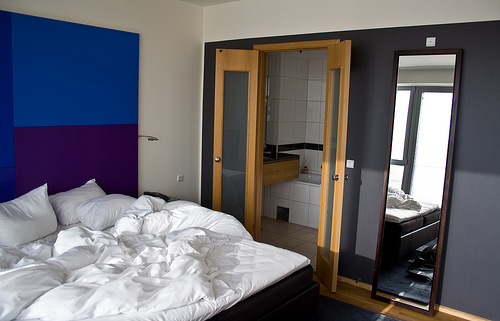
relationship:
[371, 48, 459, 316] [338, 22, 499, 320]
mirror on wall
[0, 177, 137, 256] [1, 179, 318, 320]
pillows on bed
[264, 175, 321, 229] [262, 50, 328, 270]
tub in bathroom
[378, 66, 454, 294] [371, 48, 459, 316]
reflection in mirror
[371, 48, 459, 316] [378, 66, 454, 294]
mirror with a reflection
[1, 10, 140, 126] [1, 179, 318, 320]
blue wall decoration behind bed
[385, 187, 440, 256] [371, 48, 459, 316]
reflection of bed in mirror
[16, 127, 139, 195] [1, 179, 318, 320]
purple wall behind bed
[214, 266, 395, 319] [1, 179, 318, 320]
footboard for bed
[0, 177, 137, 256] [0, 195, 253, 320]
pillows and sheets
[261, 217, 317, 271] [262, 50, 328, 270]
floor of bathroom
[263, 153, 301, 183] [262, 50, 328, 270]
counter in bathroom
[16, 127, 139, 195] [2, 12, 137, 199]
purple wall on headboard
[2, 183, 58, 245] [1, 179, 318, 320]
pillow on bed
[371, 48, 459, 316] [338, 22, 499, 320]
mirror against wall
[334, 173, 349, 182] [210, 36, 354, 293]
handle on doors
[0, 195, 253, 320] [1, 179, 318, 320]
sheets on bed